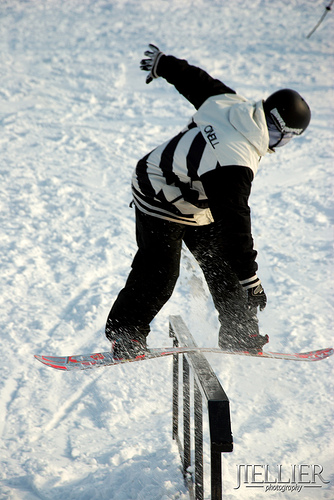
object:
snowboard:
[29, 342, 333, 371]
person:
[104, 42, 311, 358]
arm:
[158, 51, 233, 104]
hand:
[138, 41, 166, 85]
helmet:
[263, 89, 312, 149]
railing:
[168, 312, 234, 498]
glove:
[243, 278, 267, 312]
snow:
[2, 3, 331, 498]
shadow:
[23, 445, 184, 499]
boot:
[216, 311, 270, 355]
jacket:
[132, 52, 272, 290]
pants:
[106, 203, 265, 327]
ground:
[2, 0, 333, 498]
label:
[232, 461, 329, 492]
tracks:
[3, 261, 111, 428]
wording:
[202, 123, 220, 149]